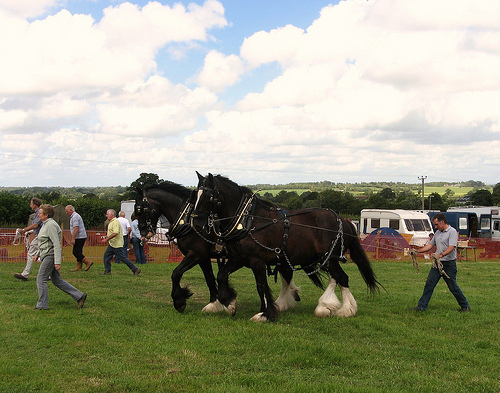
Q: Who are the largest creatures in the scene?
A: Two horses.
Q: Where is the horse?
A: On grass.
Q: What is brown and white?
A: Horse.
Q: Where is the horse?
A: In grass.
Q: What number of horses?
A: Two.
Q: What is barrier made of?
A: Plastic.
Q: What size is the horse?
A: Large.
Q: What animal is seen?
A: Horse.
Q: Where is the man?
A: Behind horse.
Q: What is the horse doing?
A: Running.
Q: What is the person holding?
A: Rope.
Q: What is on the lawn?
A: Grass.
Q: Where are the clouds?
A: In the sky.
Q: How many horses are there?
A: 2.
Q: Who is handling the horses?
A: A man.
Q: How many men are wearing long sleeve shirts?
A: 1.